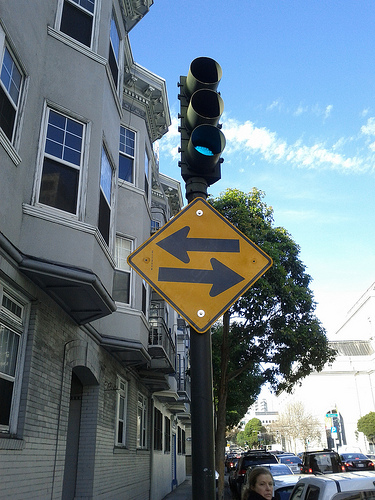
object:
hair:
[244, 467, 276, 493]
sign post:
[126, 55, 276, 499]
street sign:
[123, 192, 274, 337]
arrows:
[156, 225, 241, 266]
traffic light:
[182, 54, 227, 176]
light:
[186, 123, 227, 170]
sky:
[127, 0, 375, 345]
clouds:
[283, 151, 295, 161]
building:
[0, 0, 191, 500]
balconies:
[148, 315, 177, 373]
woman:
[240, 452, 279, 472]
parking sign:
[330, 426, 337, 433]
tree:
[356, 410, 375, 447]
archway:
[52, 337, 102, 498]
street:
[226, 451, 375, 499]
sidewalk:
[158, 471, 232, 500]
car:
[339, 452, 375, 473]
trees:
[210, 321, 263, 499]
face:
[251, 470, 275, 499]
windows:
[21, 95, 93, 235]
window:
[22, 97, 98, 235]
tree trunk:
[216, 305, 233, 499]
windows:
[114, 373, 128, 449]